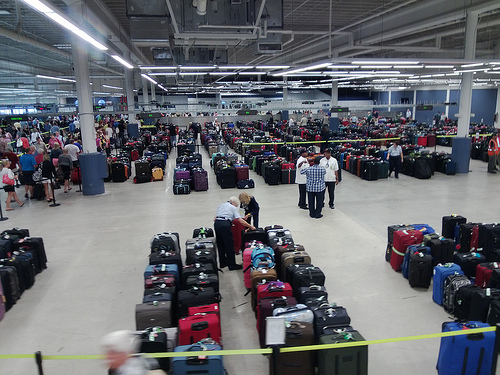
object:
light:
[110, 52, 136, 71]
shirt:
[299, 164, 328, 192]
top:
[320, 155, 339, 182]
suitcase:
[135, 301, 172, 330]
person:
[212, 193, 254, 270]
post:
[65, 48, 111, 196]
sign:
[264, 316, 288, 347]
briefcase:
[305, 298, 333, 310]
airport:
[1, 0, 500, 374]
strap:
[240, 137, 399, 149]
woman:
[384, 139, 406, 181]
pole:
[449, 7, 483, 180]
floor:
[47, 208, 132, 329]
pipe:
[164, 26, 261, 47]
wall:
[374, 88, 499, 131]